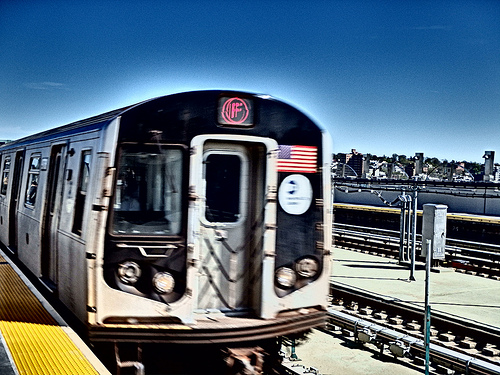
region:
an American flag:
[275, 137, 324, 176]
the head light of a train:
[148, 267, 180, 297]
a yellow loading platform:
[0, 250, 102, 373]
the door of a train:
[186, 141, 259, 318]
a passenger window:
[58, 145, 96, 242]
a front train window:
[103, 145, 189, 245]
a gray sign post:
[410, 229, 440, 374]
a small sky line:
[330, 140, 499, 195]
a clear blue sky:
[0, 1, 499, 166]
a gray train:
[0, 82, 365, 343]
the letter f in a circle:
[214, 91, 255, 131]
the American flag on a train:
[270, 135, 326, 175]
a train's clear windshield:
[105, 138, 190, 248]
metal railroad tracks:
[335, 269, 498, 374]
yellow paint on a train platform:
[3, 321, 108, 374]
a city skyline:
[336, 146, 498, 181]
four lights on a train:
[96, 249, 331, 299]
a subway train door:
[36, 137, 75, 311]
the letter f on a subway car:
[219, 91, 257, 134]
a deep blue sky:
[4, 8, 488, 85]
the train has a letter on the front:
[185, 82, 304, 166]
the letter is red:
[175, 71, 304, 178]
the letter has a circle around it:
[213, 91, 274, 141]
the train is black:
[31, 104, 386, 373]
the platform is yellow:
[10, 216, 97, 371]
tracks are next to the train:
[305, 202, 495, 370]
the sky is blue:
[16, 13, 376, 118]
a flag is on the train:
[260, 134, 356, 191]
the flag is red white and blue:
[259, 123, 377, 229]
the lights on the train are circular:
[88, 231, 362, 353]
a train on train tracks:
[3, 73, 409, 374]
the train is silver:
[9, 63, 364, 345]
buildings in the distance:
[344, 141, 494, 214]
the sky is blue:
[6, 3, 492, 191]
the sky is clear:
[0, 5, 487, 162]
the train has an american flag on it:
[259, 127, 324, 189]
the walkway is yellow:
[0, 253, 113, 371]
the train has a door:
[86, 74, 353, 356]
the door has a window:
[189, 136, 256, 321]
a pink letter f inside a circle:
[206, 88, 273, 140]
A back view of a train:
[61, 57, 351, 362]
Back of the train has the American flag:
[275, 126, 321, 176]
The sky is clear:
[5, 5, 485, 155]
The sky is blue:
[10, 5, 490, 145]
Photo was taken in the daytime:
[5, 5, 490, 371]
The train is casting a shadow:
[0, 240, 65, 345]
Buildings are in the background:
[340, 135, 495, 185]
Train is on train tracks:
[75, 285, 495, 370]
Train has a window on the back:
[105, 136, 186, 246]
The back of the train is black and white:
[83, 85, 343, 331]